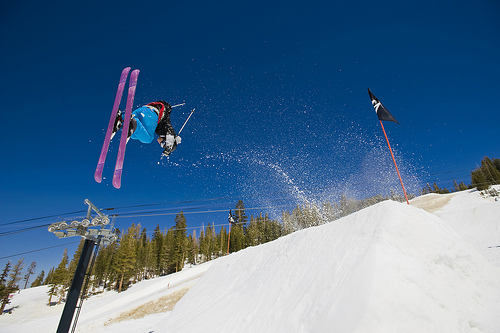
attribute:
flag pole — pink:
[355, 86, 408, 206]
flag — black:
[357, 85, 403, 130]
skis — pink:
[99, 60, 137, 189]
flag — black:
[347, 76, 422, 136]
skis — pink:
[92, 65, 140, 187]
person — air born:
[62, 54, 204, 136]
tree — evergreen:
[135, 215, 226, 287]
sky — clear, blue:
[0, 2, 498, 289]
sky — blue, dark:
[6, 0, 496, 155]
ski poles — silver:
[163, 96, 199, 148]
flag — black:
[345, 90, 446, 175]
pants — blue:
[88, 112, 150, 153]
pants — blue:
[122, 102, 159, 147]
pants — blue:
[121, 107, 160, 143]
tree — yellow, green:
[172, 210, 186, 275]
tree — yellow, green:
[162, 222, 179, 277]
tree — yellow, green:
[119, 220, 139, 285]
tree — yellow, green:
[234, 197, 249, 254]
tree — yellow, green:
[202, 218, 216, 266]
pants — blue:
[103, 110, 178, 148]